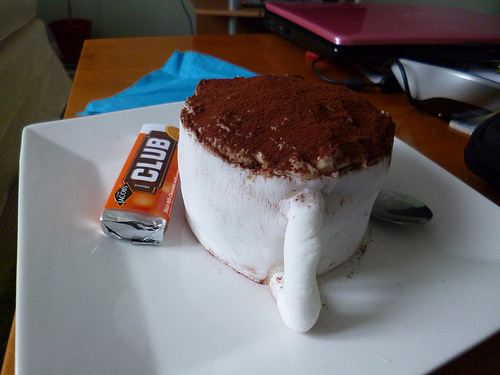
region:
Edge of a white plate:
[16, 114, 68, 139]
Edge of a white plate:
[76, 104, 153, 124]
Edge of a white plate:
[133, 90, 178, 122]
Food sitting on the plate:
[30, 58, 403, 327]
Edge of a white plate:
[420, 149, 473, 204]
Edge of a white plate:
[468, 178, 497, 225]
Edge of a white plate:
[421, 341, 498, 372]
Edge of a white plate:
[3, 276, 39, 374]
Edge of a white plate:
[6, 154, 39, 253]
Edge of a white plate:
[8, 109, 58, 194]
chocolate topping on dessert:
[183, 80, 369, 170]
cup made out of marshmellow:
[192, 169, 379, 331]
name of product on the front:
[119, 127, 170, 269]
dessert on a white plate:
[31, 115, 486, 372]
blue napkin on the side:
[91, 58, 208, 112]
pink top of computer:
[266, 11, 498, 54]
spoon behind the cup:
[383, 190, 428, 240]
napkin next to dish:
[105, 55, 227, 111]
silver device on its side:
[402, 58, 493, 115]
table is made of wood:
[59, 35, 165, 82]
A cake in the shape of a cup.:
[177, 71, 396, 331]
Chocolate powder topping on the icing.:
[181, 76, 396, 176]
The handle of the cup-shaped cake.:
[270, 188, 326, 332]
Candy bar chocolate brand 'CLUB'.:
[100, 123, 177, 243]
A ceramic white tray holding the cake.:
[13, 100, 498, 373]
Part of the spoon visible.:
[370, 189, 432, 227]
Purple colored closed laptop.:
[263, 2, 498, 60]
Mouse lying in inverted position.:
[392, 55, 499, 116]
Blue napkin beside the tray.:
[80, 50, 255, 115]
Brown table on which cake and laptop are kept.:
[2, 32, 497, 374]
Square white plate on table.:
[1, 98, 495, 362]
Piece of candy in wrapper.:
[100, 114, 181, 247]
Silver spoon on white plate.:
[373, 189, 437, 228]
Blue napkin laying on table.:
[78, 47, 272, 117]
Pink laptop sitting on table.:
[255, 1, 498, 73]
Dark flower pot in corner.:
[45, 14, 94, 64]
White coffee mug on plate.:
[178, 67, 400, 332]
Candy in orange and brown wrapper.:
[97, 122, 186, 246]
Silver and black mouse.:
[386, 50, 496, 121]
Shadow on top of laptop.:
[261, 1, 379, 40]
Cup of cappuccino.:
[77, 57, 475, 349]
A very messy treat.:
[57, 29, 476, 348]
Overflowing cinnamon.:
[178, 58, 435, 198]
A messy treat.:
[15, 35, 489, 363]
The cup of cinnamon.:
[88, 49, 495, 358]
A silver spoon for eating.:
[365, 168, 458, 254]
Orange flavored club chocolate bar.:
[81, 93, 196, 256]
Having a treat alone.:
[13, 7, 490, 369]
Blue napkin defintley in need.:
[80, 40, 270, 120]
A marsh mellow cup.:
[147, 67, 441, 365]